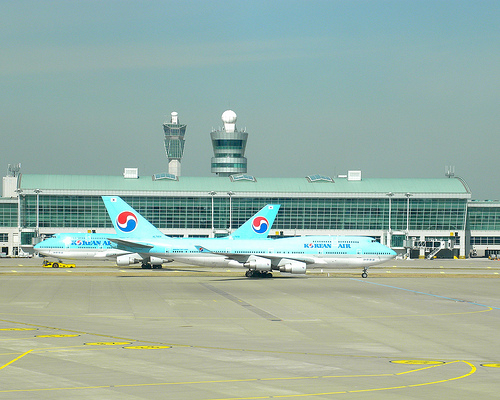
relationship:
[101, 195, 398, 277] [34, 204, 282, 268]
airplane pointed away from airplane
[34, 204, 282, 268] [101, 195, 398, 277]
airplane pointed away from airplane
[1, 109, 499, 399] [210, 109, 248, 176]
airport has a control tower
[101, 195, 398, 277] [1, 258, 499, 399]
airplane on tarmac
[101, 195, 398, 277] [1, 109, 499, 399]
airplane at airport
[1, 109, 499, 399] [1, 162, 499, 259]
airport has a terminal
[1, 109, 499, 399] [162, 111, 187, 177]
airport has a control tower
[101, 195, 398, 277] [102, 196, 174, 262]
airplane has a tail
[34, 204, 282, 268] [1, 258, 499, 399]
airplane on tarmac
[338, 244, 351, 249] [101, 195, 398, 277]
word air on side of an airplane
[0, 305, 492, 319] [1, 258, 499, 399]
line on tarmac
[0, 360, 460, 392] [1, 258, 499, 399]
line on tarmac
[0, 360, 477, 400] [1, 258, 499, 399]
line on tarmac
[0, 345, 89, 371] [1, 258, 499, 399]
line on tarmac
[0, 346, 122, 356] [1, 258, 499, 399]
line on tarmac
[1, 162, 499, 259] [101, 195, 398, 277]
terminal behind airplane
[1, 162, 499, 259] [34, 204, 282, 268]
terminal behind airplane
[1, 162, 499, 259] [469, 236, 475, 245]
terminal has a window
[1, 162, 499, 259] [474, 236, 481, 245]
terminal has a window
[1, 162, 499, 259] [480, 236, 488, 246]
terminal has a window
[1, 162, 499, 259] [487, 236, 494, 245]
terminal has a window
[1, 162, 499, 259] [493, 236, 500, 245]
terminal has a window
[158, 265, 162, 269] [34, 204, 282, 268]
wheel under airplane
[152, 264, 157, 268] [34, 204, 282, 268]
wheel under airplane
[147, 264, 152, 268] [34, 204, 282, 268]
wheel under airplane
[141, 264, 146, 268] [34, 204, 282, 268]
wheel under airplane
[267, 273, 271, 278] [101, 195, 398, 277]
wheel under airplane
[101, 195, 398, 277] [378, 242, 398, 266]
airplane has a nose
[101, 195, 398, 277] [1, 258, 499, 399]
airplane sitting on tarmac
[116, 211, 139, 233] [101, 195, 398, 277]
logo on airplane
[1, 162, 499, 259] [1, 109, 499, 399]
terminal at airport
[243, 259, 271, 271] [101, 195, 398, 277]
engine on airplane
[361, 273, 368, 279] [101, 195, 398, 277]
tire on airplane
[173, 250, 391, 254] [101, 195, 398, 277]
window row on side of an airplane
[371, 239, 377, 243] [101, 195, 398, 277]
windshield on airplane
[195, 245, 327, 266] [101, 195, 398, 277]
wing on side of airplane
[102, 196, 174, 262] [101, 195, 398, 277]
tail on back of an airplane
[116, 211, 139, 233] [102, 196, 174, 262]
logo on tail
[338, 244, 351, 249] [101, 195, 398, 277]
word air on an airplane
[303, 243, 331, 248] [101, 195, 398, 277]
word korean on an airplane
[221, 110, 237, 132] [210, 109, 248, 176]
object on control tower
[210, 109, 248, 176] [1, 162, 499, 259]
control tower behind terminal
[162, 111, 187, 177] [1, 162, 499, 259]
control tower behind terminal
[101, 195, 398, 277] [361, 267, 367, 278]
airplane has a landing gear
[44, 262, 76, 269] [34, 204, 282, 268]
object under airplane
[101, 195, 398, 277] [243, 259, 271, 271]
airplane has an engine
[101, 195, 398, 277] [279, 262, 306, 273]
airplane has an engine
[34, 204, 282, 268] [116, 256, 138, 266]
airplane has an engine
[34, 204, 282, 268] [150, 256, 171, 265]
airplane has an engine